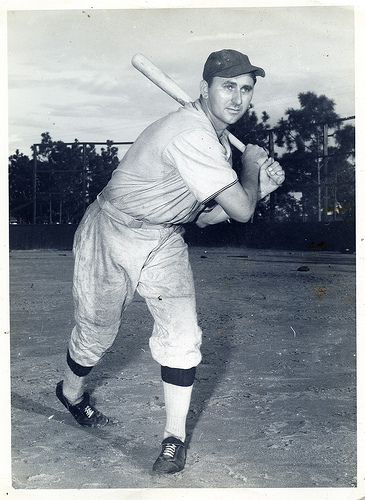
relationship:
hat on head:
[199, 49, 267, 77] [204, 74, 259, 125]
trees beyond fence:
[312, 119, 347, 220] [28, 115, 358, 249]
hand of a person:
[254, 154, 285, 197] [47, 45, 284, 473]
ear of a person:
[195, 71, 211, 103] [47, 45, 284, 473]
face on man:
[209, 74, 254, 123] [55, 49, 284, 475]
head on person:
[192, 37, 272, 138] [87, 22, 310, 339]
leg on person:
[136, 234, 201, 475] [47, 45, 284, 473]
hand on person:
[239, 141, 271, 170] [47, 45, 284, 473]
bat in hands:
[107, 36, 299, 193] [235, 139, 286, 193]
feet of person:
[46, 369, 217, 474] [47, 45, 284, 473]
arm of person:
[178, 128, 258, 220] [16, 77, 272, 359]